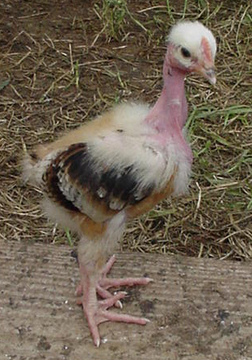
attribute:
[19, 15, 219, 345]
turkey — small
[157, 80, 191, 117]
neck — red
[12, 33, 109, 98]
grass — brown and green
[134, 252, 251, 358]
mat — brown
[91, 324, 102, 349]
claw — small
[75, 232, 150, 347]
leg — part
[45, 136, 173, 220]
feathers — BROWN, WHITE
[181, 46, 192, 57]
eye — small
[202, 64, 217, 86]
beak — brown and white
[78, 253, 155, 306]
claw — pink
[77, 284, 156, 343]
claw — pink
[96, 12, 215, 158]
bird — baby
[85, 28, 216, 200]
turkey — baby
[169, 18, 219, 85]
head — baby turkey's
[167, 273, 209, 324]
mat — brown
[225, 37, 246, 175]
straw — green and brown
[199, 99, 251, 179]
hay — green and brown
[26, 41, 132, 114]
grass — on ground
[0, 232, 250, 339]
plank — wooden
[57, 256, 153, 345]
feet — pink, chicken feet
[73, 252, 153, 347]
claw — pink 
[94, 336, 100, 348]
nail — white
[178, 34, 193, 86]
eye — black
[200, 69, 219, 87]
beak — yellow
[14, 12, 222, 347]
bird — young, baby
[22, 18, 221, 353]
baby bird — Baby 